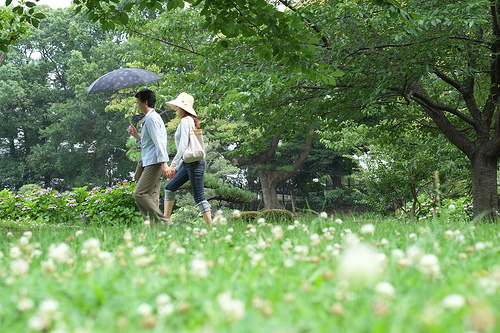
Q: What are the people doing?
A: Walking.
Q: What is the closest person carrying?
A: Umbrella.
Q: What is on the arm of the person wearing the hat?
A: Purse.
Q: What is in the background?
A: Trees.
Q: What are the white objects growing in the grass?
A: Flowers.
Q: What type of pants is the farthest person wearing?
A: Jeans.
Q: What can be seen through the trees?
A: Clouds.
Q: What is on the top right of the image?
A: Tree.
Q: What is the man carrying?
A: Umbrella.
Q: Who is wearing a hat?
A: The woman.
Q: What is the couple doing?
A: Walking.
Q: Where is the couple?
A: Park.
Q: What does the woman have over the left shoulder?
A: Bag.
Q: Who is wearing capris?
A: The woman.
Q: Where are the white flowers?
A: Foreground.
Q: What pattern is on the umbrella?
A: Polka dots.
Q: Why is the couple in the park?
A: For a walk.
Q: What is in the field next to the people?
A: Green grass and white flowers.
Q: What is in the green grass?
A: White flowers.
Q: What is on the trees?
A: Green leaves.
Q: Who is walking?
A: A man and a woman.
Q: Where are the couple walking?
A: Through a park.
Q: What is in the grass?
A: Flowers.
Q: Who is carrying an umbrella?
A: The man.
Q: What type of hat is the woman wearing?
A: Straw.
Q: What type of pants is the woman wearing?
A: Capris.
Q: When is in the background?
A: Trees.